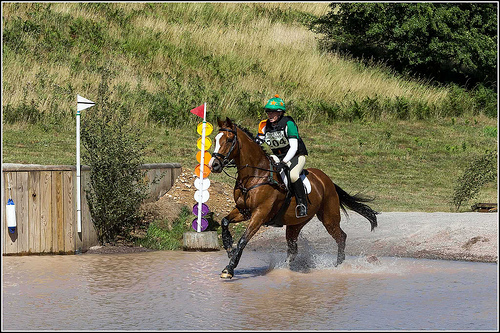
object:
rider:
[255, 94, 308, 218]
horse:
[207, 116, 381, 279]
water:
[130, 254, 227, 325]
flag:
[188, 101, 206, 122]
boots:
[291, 179, 308, 218]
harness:
[204, 142, 281, 193]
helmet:
[262, 94, 286, 112]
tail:
[334, 183, 382, 232]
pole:
[75, 111, 81, 233]